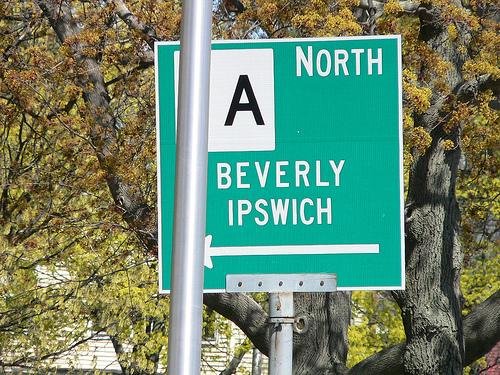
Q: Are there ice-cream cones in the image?
A: No, there are no ice-cream cones.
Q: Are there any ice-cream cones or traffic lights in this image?
A: No, there are no ice-cream cones or traffic lights.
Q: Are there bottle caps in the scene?
A: No, there are no bottle caps.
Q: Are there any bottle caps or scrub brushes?
A: No, there are no bottle caps or scrub brushes.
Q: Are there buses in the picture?
A: No, there are no buses.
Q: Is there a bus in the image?
A: No, there are no buses.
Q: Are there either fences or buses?
A: No, there are no buses or fences.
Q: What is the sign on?
A: The sign is on the pole.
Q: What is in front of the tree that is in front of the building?
A: The sign is in front of the tree.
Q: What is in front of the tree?
A: The sign is in front of the tree.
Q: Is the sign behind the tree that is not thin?
A: No, the sign is in front of the tree.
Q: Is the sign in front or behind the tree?
A: The sign is in front of the tree.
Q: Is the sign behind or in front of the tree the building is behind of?
A: The sign is in front of the tree.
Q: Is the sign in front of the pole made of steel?
A: No, the sign is behind the pole.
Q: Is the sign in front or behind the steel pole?
A: The sign is behind the pole.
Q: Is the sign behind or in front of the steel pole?
A: The sign is behind the pole.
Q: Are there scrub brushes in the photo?
A: No, there are no scrub brushes.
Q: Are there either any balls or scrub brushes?
A: No, there are no scrub brushes or balls.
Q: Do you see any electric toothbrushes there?
A: No, there are no electric toothbrushes.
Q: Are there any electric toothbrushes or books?
A: No, there are no electric toothbrushes or books.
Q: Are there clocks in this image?
A: No, there are no clocks.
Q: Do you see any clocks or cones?
A: No, there are no clocks or cones.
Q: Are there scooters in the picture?
A: No, there are no scooters.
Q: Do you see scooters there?
A: No, there are no scooters.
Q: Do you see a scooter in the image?
A: No, there are no scooters.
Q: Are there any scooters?
A: No, there are no scooters.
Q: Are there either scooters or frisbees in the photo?
A: No, there are no scooters or frisbees.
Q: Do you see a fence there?
A: No, there are no fences.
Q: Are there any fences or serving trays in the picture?
A: No, there are no fences or serving trays.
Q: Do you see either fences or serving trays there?
A: No, there are no fences or serving trays.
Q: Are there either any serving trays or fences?
A: No, there are no fences or serving trays.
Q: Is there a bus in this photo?
A: No, there are no buses.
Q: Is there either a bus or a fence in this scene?
A: No, there are no buses or fences.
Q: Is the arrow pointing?
A: Yes, the arrow is pointing.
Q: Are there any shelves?
A: No, there are no shelves.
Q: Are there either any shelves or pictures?
A: No, there are no shelves or pictures.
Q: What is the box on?
A: The box is on the sign.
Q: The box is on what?
A: The box is on the sign.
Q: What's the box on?
A: The box is on the sign.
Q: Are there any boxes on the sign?
A: Yes, there is a box on the sign.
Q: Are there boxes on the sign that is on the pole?
A: Yes, there is a box on the sign.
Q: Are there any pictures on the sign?
A: No, there is a box on the sign.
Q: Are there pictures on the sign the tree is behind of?
A: No, there is a box on the sign.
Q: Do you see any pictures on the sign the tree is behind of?
A: No, there is a box on the sign.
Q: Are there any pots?
A: No, there are no pots.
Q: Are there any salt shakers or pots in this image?
A: No, there are no pots or salt shakers.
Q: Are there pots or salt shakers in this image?
A: No, there are no pots or salt shakers.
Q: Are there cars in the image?
A: No, there are no cars.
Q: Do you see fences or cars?
A: No, there are no cars or fences.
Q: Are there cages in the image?
A: No, there are no cages.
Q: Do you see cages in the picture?
A: No, there are no cages.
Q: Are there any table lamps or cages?
A: No, there are no cages or table lamps.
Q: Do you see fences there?
A: No, there are no fences.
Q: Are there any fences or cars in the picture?
A: No, there are no fences or cars.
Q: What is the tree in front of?
A: The tree is in front of the building.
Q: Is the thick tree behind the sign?
A: Yes, the tree is behind the sign.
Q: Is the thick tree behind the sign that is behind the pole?
A: Yes, the tree is behind the sign.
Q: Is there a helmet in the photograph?
A: No, there are no helmets.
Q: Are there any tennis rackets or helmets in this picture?
A: No, there are no helmets or tennis rackets.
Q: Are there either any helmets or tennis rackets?
A: No, there are no helmets or tennis rackets.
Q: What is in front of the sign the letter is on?
A: The pole is in front of the sign.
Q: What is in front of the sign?
A: The pole is in front of the sign.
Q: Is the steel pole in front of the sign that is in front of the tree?
A: Yes, the pole is in front of the sign.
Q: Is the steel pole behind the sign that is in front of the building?
A: No, the pole is in front of the sign.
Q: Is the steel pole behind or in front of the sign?
A: The pole is in front of the sign.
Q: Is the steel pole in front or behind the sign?
A: The pole is in front of the sign.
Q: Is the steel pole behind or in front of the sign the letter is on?
A: The pole is in front of the sign.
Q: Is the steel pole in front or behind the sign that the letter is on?
A: The pole is in front of the sign.